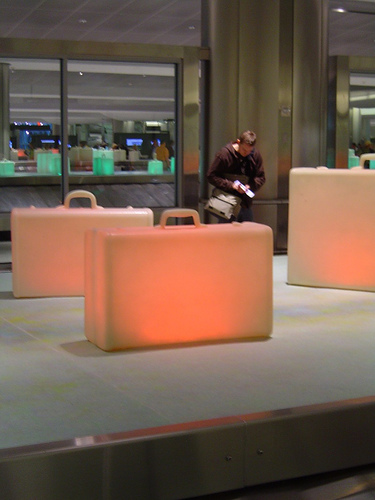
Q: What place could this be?
A: It is a sidewalk.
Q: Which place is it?
A: It is a sidewalk.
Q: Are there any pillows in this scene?
A: No, there are no pillows.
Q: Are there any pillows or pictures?
A: No, there are no pillows or pictures.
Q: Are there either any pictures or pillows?
A: No, there are no pillows or pictures.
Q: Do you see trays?
A: No, there are no trays.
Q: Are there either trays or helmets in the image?
A: No, there are no trays or helmets.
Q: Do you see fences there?
A: No, there are no fences.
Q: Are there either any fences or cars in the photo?
A: No, there are no fences or cars.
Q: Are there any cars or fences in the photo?
A: No, there are no fences or cars.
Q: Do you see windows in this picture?
A: Yes, there is a window.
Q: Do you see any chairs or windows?
A: Yes, there is a window.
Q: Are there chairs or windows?
A: Yes, there is a window.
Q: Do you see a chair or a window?
A: Yes, there is a window.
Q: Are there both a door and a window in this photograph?
A: No, there is a window but no doors.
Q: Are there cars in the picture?
A: No, there are no cars.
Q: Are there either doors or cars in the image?
A: No, there are no cars or doors.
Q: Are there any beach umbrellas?
A: No, there are no beach umbrellas.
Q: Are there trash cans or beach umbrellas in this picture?
A: No, there are no beach umbrellas or trash cans.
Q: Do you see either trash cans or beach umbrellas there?
A: No, there are no beach umbrellas or trash cans.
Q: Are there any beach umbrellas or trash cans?
A: No, there are no beach umbrellas or trash cans.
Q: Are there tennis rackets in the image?
A: No, there are no tennis rackets.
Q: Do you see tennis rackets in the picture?
A: No, there are no tennis rackets.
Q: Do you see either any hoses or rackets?
A: No, there are no rackets or hoses.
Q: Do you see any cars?
A: No, there are no cars.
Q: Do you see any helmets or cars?
A: No, there are no cars or helmets.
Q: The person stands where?
A: The person stands on the sidewalk.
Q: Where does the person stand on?
A: The person stands on the sidewalk.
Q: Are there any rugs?
A: No, there are no rugs.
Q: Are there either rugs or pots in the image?
A: No, there are no rugs or pots.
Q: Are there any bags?
A: Yes, there is a bag.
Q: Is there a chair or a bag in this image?
A: Yes, there is a bag.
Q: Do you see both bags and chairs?
A: No, there is a bag but no chairs.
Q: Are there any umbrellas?
A: No, there are no umbrellas.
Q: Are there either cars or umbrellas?
A: No, there are no umbrellas or cars.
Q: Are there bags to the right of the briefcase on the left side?
A: Yes, there is a bag to the right of the briefcase.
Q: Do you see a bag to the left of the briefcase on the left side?
A: No, the bag is to the right of the briefcase.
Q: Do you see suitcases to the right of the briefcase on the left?
A: No, there is a bag to the right of the briefcase.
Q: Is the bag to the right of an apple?
A: No, the bag is to the right of a briefcase.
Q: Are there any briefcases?
A: Yes, there is a briefcase.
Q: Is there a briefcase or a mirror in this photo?
A: Yes, there is a briefcase.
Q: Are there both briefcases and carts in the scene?
A: No, there is a briefcase but no carts.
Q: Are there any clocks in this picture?
A: No, there are no clocks.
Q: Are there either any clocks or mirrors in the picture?
A: No, there are no clocks or mirrors.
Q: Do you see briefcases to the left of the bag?
A: Yes, there is a briefcase to the left of the bag.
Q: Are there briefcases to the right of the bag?
A: No, the briefcase is to the left of the bag.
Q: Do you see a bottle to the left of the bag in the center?
A: No, there is a briefcase to the left of the bag.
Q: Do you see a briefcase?
A: Yes, there is a briefcase.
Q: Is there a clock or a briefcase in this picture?
A: Yes, there is a briefcase.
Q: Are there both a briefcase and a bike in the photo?
A: No, there is a briefcase but no bikes.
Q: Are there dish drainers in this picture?
A: No, there are no dish drainers.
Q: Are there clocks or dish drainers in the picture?
A: No, there are no dish drainers or clocks.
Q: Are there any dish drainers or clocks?
A: No, there are no dish drainers or clocks.